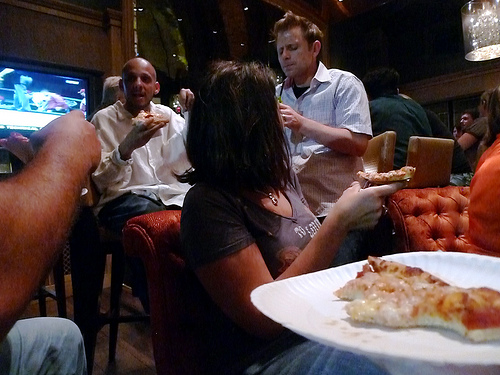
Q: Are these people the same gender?
A: No, they are both male and female.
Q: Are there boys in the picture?
A: No, there are no boys.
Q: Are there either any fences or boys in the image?
A: No, there are no boys or fences.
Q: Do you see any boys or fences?
A: No, there are no boys or fences.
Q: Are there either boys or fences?
A: No, there are no boys or fences.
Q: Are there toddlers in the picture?
A: No, there are no toddlers.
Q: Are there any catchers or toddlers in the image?
A: No, there are no toddlers or catchers.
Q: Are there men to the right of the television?
A: Yes, there is a man to the right of the television.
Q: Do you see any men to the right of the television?
A: Yes, there is a man to the right of the television.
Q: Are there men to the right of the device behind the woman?
A: Yes, there is a man to the right of the television.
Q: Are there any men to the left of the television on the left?
A: No, the man is to the right of the TV.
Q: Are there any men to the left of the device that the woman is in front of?
A: No, the man is to the right of the TV.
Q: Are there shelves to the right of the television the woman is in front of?
A: No, there is a man to the right of the television.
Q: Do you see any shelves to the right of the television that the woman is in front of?
A: No, there is a man to the right of the television.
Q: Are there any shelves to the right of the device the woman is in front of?
A: No, there is a man to the right of the television.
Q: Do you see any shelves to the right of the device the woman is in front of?
A: No, there is a man to the right of the television.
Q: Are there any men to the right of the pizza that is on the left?
A: Yes, there is a man to the right of the pizza.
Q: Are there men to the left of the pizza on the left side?
A: No, the man is to the right of the pizza.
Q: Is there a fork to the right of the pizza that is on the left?
A: No, there is a man to the right of the pizza.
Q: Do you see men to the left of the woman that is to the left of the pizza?
A: Yes, there is a man to the left of the woman.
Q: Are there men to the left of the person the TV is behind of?
A: Yes, there is a man to the left of the woman.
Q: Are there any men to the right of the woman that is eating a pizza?
A: No, the man is to the left of the woman.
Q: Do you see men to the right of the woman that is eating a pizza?
A: No, the man is to the left of the woman.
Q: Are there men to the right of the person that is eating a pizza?
A: No, the man is to the left of the woman.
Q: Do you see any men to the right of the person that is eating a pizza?
A: No, the man is to the left of the woman.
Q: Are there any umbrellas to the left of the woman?
A: No, there is a man to the left of the woman.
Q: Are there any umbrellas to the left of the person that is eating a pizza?
A: No, there is a man to the left of the woman.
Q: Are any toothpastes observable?
A: No, there are no toothpastes.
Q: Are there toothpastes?
A: No, there are no toothpastes.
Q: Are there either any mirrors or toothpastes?
A: No, there are no toothpastes or mirrors.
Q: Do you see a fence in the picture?
A: No, there are no fences.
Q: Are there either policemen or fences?
A: No, there are no fences or policemen.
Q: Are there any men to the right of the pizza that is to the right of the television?
A: Yes, there is a man to the right of the pizza.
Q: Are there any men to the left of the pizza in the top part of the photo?
A: No, the man is to the right of the pizza.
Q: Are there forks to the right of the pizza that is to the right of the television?
A: No, there is a man to the right of the pizza.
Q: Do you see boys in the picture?
A: No, there are no boys.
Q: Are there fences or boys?
A: No, there are no boys or fences.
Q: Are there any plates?
A: Yes, there is a plate.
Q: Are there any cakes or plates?
A: Yes, there is a plate.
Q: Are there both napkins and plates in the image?
A: No, there is a plate but no napkins.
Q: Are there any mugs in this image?
A: No, there are no mugs.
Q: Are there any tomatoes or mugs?
A: No, there are no mugs or tomatoes.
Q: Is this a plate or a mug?
A: This is a plate.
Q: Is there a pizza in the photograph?
A: Yes, there is a pizza.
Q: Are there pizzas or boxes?
A: Yes, there is a pizza.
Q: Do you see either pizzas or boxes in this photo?
A: Yes, there is a pizza.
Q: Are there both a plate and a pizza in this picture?
A: Yes, there are both a pizza and a plate.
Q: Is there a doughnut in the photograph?
A: No, there are no donuts.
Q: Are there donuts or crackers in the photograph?
A: No, there are no donuts or crackers.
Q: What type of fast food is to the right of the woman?
A: The food is a pizza.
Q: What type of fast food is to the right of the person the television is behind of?
A: The food is a pizza.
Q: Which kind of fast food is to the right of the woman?
A: The food is a pizza.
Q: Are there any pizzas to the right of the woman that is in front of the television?
A: Yes, there is a pizza to the right of the woman.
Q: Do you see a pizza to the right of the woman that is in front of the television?
A: Yes, there is a pizza to the right of the woman.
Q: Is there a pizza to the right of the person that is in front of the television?
A: Yes, there is a pizza to the right of the woman.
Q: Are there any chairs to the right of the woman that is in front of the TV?
A: No, there is a pizza to the right of the woman.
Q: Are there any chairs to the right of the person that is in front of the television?
A: No, there is a pizza to the right of the woman.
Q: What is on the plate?
A: The pizza is on the plate.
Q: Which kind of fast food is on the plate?
A: The food is a pizza.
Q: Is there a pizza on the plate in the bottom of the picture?
A: Yes, there is a pizza on the plate.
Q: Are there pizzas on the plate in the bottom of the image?
A: Yes, there is a pizza on the plate.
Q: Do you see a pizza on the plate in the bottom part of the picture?
A: Yes, there is a pizza on the plate.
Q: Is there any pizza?
A: Yes, there is a pizza.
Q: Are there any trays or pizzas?
A: Yes, there is a pizza.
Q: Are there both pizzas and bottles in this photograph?
A: No, there is a pizza but no bottles.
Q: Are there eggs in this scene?
A: No, there are no eggs.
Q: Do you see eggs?
A: No, there are no eggs.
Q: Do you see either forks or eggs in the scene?
A: No, there are no eggs or forks.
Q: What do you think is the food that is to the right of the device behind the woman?
A: The food is a pizza.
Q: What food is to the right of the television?
A: The food is a pizza.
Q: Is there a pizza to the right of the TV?
A: Yes, there is a pizza to the right of the TV.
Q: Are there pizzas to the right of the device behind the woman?
A: Yes, there is a pizza to the right of the TV.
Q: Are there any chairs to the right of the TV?
A: No, there is a pizza to the right of the TV.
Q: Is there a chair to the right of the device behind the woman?
A: No, there is a pizza to the right of the TV.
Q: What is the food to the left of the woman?
A: The food is a pizza.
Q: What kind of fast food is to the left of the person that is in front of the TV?
A: The food is a pizza.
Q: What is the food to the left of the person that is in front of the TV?
A: The food is a pizza.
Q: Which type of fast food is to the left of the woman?
A: The food is a pizza.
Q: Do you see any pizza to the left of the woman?
A: Yes, there is a pizza to the left of the woman.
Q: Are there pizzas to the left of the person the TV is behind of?
A: Yes, there is a pizza to the left of the woman.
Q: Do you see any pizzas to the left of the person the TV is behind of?
A: Yes, there is a pizza to the left of the woman.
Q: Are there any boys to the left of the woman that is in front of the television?
A: No, there is a pizza to the left of the woman.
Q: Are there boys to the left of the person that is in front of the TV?
A: No, there is a pizza to the left of the woman.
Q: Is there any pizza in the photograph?
A: Yes, there is a pizza.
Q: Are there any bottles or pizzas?
A: Yes, there is a pizza.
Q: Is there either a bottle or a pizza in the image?
A: Yes, there is a pizza.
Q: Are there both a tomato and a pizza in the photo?
A: No, there is a pizza but no tomatoes.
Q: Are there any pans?
A: No, there are no pans.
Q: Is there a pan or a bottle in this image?
A: No, there are no pans or bottles.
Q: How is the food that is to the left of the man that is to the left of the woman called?
A: The food is a pizza.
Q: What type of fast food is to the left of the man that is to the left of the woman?
A: The food is a pizza.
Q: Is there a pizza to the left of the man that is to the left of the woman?
A: Yes, there is a pizza to the left of the man.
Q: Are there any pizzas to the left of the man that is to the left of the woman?
A: Yes, there is a pizza to the left of the man.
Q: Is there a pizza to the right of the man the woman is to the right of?
A: No, the pizza is to the left of the man.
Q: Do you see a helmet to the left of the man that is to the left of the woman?
A: No, there is a pizza to the left of the man.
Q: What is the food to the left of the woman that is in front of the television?
A: The food is a pizza.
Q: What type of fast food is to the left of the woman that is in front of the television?
A: The food is a pizza.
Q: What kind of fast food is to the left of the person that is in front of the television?
A: The food is a pizza.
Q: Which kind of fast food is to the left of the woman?
A: The food is a pizza.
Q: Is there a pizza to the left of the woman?
A: Yes, there is a pizza to the left of the woman.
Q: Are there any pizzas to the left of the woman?
A: Yes, there is a pizza to the left of the woman.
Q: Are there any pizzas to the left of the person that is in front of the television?
A: Yes, there is a pizza to the left of the woman.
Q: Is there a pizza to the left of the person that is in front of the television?
A: Yes, there is a pizza to the left of the woman.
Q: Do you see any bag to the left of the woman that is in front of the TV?
A: No, there is a pizza to the left of the woman.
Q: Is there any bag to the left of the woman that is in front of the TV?
A: No, there is a pizza to the left of the woman.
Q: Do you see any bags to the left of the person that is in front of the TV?
A: No, there is a pizza to the left of the woman.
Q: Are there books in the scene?
A: No, there are no books.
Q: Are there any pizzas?
A: Yes, there is a pizza.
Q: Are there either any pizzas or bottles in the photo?
A: Yes, there is a pizza.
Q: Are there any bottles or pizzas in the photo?
A: Yes, there is a pizza.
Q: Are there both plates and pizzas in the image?
A: Yes, there are both a pizza and a plate.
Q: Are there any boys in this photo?
A: No, there are no boys.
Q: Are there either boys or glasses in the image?
A: No, there are no boys or glasses.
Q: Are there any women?
A: Yes, there is a woman.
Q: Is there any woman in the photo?
A: Yes, there is a woman.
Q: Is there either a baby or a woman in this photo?
A: Yes, there is a woman.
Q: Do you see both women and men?
A: Yes, there are both a woman and a man.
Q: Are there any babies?
A: No, there are no babies.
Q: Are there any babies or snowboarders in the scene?
A: No, there are no babies or snowboarders.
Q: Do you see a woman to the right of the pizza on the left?
A: Yes, there is a woman to the right of the pizza.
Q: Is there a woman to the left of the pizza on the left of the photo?
A: No, the woman is to the right of the pizza.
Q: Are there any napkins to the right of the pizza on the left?
A: No, there is a woman to the right of the pizza.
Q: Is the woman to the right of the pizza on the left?
A: Yes, the woman is to the right of the pizza.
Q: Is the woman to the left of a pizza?
A: No, the woman is to the right of a pizza.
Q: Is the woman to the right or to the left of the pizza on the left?
A: The woman is to the right of the pizza.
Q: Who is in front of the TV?
A: The woman is in front of the TV.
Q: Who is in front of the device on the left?
A: The woman is in front of the TV.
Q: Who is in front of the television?
A: The woman is in front of the TV.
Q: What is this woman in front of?
A: The woman is in front of the television.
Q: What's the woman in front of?
A: The woman is in front of the television.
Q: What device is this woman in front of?
A: The woman is in front of the TV.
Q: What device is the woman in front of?
A: The woman is in front of the TV.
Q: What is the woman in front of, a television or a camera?
A: The woman is in front of a television.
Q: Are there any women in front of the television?
A: Yes, there is a woman in front of the television.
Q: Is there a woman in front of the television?
A: Yes, there is a woman in front of the television.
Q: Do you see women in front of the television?
A: Yes, there is a woman in front of the television.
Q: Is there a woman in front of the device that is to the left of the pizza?
A: Yes, there is a woman in front of the television.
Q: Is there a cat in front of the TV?
A: No, there is a woman in front of the TV.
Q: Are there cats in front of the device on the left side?
A: No, there is a woman in front of the TV.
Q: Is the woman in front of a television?
A: Yes, the woman is in front of a television.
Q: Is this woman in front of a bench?
A: No, the woman is in front of a television.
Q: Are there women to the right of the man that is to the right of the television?
A: Yes, there is a woman to the right of the man.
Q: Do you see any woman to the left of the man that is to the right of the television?
A: No, the woman is to the right of the man.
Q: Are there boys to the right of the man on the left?
A: No, there is a woman to the right of the man.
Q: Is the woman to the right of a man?
A: Yes, the woman is to the right of a man.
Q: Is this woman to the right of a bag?
A: No, the woman is to the right of a man.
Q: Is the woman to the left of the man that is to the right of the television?
A: No, the woman is to the right of the man.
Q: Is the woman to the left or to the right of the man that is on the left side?
A: The woman is to the right of the man.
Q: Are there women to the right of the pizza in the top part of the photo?
A: Yes, there is a woman to the right of the pizza.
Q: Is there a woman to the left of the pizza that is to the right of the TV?
A: No, the woman is to the right of the pizza.